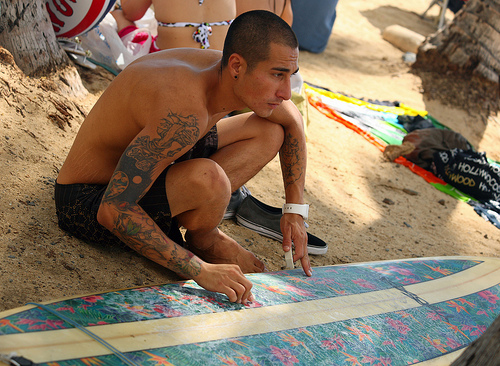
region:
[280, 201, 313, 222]
Man wearing a white wristband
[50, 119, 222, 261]
Man wearing black shorts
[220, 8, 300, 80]
Man has short black hair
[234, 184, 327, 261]
Black sneakers on the dand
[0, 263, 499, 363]
Surfboard in the sand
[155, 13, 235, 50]
Woman's swim top straps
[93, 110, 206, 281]
Man has tattoos on his arm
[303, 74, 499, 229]
Beach towel laying on the sand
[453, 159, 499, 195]
Hollywood on black object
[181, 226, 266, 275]
Man's foot are bare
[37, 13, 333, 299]
the man on the sand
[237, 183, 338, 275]
shoes beside the man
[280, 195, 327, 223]
the watch on the wrist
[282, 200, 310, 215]
the watch is white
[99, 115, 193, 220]
tattoo on the arm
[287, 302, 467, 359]
flowers on the surfboard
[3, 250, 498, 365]
the surfboard on the sand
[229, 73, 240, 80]
earring in the ear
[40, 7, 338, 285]
the man wearing shorts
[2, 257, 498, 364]
Many colored surfboard on sand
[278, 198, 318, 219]
White watch on man's wrist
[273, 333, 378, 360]
Flower patterns on surfboard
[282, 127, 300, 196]
Tattoo on man's forearm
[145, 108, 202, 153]
Tattoo on man's bicep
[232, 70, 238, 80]
Small black earring in man's ear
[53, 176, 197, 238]
Black shorts on man's legs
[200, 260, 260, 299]
Man's right hand on surfboard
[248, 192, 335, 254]
Black shoe in sand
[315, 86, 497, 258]
Towel lying on sand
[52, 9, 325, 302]
Person sitting on the beach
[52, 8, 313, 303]
Man sitting on the beach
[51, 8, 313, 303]
Male sitting on the beach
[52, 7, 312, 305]
White man sitting on the beach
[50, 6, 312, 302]
Man with arm tattoos sitting on the beach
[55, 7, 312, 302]
Man with a shaved head sitting on the beach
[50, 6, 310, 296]
Person with tattooed arms sitting down on the beach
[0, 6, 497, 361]
Man touching a surfboard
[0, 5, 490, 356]
Man touching a surfboard while sitting on the beach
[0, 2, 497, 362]
Tattooed man touching a surfboard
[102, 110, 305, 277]
A man has tatoos on his arms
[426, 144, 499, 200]
A bag has Hollywood.on it.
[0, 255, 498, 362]
A mostly blue and white surfboard is on the ground.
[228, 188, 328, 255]
Two sneakers are on the ground.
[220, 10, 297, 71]
A man has short hair.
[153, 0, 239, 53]
A white and colored string is tied on a back.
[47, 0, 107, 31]
Red letters and stripe on a white rounded surface.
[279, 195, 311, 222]
A white watch is on a wrist.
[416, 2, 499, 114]
A tree trunk is sticking out of the ground.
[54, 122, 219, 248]
A man is wearing mostly black shorts.